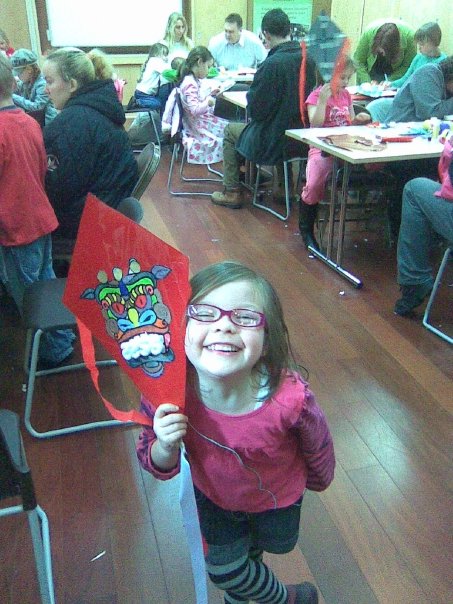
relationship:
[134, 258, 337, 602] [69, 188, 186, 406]
child holding kite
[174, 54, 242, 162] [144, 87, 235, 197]
girl sitting on chair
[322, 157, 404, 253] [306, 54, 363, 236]
girl sitting on chair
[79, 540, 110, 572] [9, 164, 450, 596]
trash on floor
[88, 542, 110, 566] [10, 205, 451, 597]
trash on floor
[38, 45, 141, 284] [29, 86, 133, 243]
person wearing hoodie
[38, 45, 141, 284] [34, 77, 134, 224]
person wearing hoodie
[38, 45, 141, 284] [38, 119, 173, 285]
person sitting in chair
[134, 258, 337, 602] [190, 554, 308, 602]
child wearing leggings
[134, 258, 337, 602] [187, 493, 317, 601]
child has legs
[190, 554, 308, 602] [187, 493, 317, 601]
leggings are on legs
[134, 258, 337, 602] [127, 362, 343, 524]
child wearing shirt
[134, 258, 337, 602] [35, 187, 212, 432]
child holding kite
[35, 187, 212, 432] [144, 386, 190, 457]
kite in hand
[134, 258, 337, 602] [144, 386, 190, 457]
child has hand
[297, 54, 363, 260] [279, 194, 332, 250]
girl wearing boots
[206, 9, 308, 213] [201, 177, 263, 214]
person wearing boot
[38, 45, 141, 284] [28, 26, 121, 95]
person has hair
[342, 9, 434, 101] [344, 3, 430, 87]
person wearing shirt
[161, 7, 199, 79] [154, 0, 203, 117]
people has hair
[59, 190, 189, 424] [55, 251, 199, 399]
kite has face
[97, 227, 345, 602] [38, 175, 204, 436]
child holding kite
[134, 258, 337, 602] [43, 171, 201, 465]
child holding kite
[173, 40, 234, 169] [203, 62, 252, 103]
girl reading book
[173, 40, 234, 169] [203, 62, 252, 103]
girl wearing book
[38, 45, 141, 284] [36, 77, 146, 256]
person wearing coat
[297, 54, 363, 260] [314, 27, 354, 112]
girl holding kite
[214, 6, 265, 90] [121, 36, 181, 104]
man watching girl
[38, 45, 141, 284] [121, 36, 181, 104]
person watching girl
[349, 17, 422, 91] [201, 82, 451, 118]
person leaning over table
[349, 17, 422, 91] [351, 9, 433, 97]
person wearing jacket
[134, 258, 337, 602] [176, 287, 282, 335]
child wearing glasses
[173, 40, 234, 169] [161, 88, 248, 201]
girl sitting in chair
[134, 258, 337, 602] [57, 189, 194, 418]
child holding kite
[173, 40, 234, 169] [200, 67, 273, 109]
girl sitting at table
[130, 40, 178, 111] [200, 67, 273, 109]
girl sitting at table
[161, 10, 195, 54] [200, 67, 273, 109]
people sitting at table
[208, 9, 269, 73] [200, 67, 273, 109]
man sitting at table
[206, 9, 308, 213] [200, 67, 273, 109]
person sitting at table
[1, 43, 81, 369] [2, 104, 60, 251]
person wearing shirt